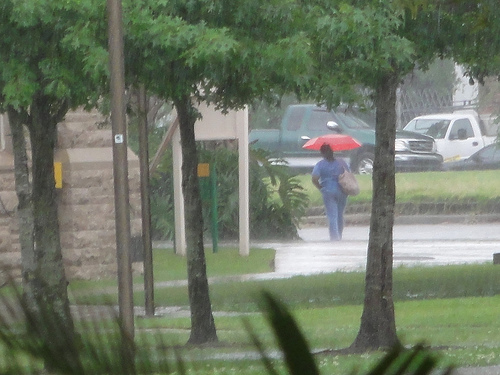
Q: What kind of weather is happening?
A: Rain.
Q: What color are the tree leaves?
A: Green.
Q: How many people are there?
A: One.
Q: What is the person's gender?
A: Female.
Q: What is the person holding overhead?
A: An umbrella.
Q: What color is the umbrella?
A: Red.